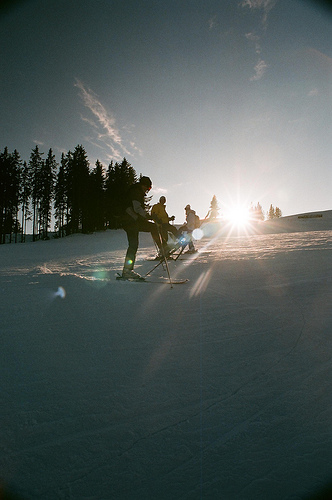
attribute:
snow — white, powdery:
[2, 211, 330, 499]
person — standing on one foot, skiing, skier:
[118, 175, 168, 281]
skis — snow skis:
[116, 277, 189, 287]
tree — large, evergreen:
[104, 157, 140, 226]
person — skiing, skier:
[176, 205, 197, 254]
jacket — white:
[185, 211, 197, 232]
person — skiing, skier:
[150, 196, 190, 258]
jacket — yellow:
[150, 203, 168, 228]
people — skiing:
[117, 176, 203, 280]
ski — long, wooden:
[144, 238, 193, 277]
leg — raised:
[139, 222, 170, 257]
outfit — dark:
[119, 184, 168, 270]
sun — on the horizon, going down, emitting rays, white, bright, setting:
[215, 201, 260, 235]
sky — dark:
[0, 1, 331, 234]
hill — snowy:
[0, 210, 331, 498]